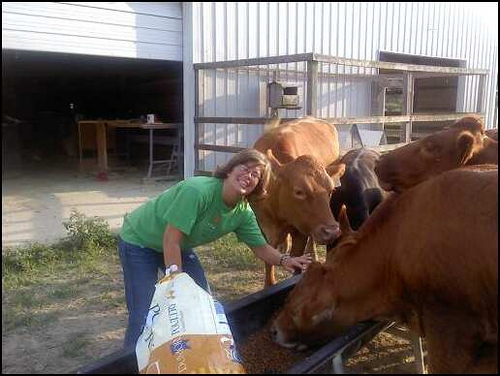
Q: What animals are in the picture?
A: Cows.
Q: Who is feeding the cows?
A: A woman.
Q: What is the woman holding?
A: A bag of cow feed.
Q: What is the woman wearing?
A: A green shirt.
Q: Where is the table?
A: Inside the barn.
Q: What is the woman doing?
A: Petting a cow.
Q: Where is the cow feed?
A: On the bin.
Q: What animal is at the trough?
A: Cows.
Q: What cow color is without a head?
A: Black.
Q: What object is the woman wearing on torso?
A: T-Shirt.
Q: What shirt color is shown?
A: Green.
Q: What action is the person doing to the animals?
A: Feeding.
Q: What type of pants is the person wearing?
A: Blue jeans.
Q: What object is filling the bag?
A: Feed.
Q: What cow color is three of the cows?
A: Brown.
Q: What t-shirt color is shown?
A: Green.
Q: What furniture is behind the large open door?
A: Table.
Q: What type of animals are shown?
A: Cows.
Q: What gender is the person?
A: Female.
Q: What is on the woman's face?
A: Glasses.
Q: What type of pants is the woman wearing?
A: Blue jeans.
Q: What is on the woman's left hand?
A: Watch.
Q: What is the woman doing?
A: Feeding the cows.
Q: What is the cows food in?
A: A trough.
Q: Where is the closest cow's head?
A: Inside the trough.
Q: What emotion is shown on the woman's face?
A: Joy.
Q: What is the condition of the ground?
A: Nearly bard.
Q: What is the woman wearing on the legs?
A: Blue Jeans.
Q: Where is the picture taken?
A: Probably a farm.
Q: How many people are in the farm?
A: One.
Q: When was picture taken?
A: Daytime.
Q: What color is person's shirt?
A: Green.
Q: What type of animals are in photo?
A: Cows.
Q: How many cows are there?
A: About four.